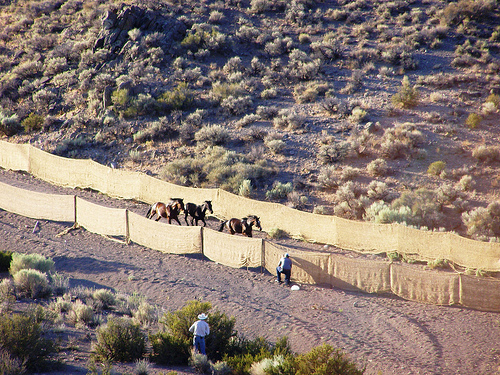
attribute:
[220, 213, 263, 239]
horse — walking, brown, wild, dark brown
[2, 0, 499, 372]
ground — dry, semi-arid, gray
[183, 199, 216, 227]
horse — wild, running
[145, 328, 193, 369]
bush — green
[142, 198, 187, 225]
horse — wild, running, brown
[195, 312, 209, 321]
hat — white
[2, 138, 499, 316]
chute — cloth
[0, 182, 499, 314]
fence — cloth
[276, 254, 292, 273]
t-shirt — white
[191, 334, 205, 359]
pants — blue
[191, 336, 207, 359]
jeans — blue